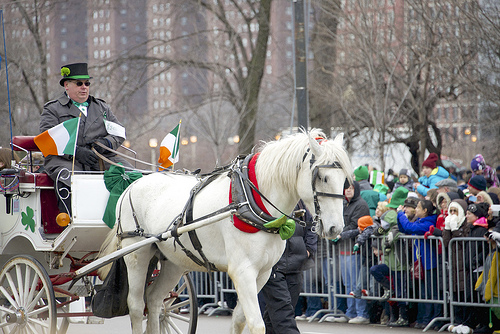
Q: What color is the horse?
A: White.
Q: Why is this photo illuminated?
A: Sunlight.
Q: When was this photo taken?
A: During the day.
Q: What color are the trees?
A: Brown.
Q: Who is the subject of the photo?
A: The horses.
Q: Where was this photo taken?
A: At a parade.